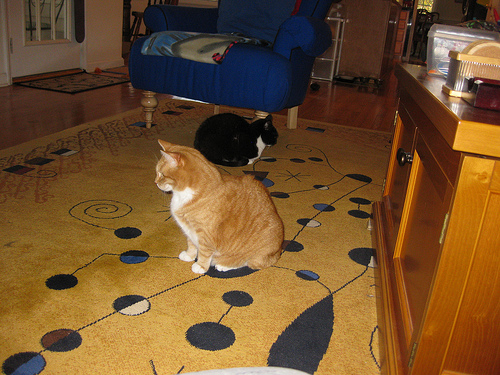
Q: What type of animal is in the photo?
A: Cats.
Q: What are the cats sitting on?
A: Rug.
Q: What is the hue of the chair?
A: Blue.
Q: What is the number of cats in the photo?
A: Two.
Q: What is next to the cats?
A: Cabinet.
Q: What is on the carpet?
A: Pattern.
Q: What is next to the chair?
A: Door.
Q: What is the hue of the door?
A: White.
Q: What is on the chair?
A: Blanket.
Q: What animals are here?
A: Two cats.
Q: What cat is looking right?
A: The black one.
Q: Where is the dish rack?
A: On the counter.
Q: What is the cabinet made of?
A: Wood.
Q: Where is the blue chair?
A: Behind the black cat.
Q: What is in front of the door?
A: Doormat.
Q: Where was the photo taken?
A: In a living room.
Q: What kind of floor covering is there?
A: A rug.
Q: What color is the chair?
A: Blue.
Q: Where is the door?
A: To the left.